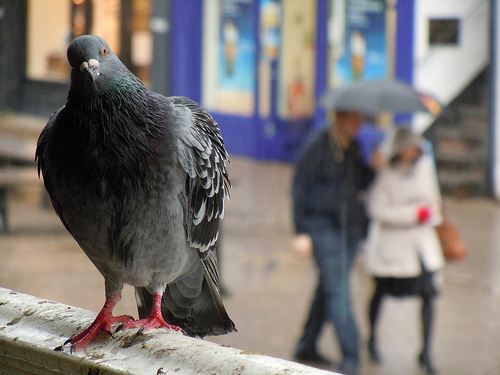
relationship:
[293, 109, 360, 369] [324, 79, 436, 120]
man holds umbrella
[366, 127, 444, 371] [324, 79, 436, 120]
woman holds umbrella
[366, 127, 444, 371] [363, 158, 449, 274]
woman wears coat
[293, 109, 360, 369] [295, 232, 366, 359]
man wears jeans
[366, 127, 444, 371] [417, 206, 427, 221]
woman wears glove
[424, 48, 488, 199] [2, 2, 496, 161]
steps by store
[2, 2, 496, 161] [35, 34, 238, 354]
store behind foreground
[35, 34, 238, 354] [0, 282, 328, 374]
foreground on railing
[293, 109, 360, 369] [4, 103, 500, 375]
man on street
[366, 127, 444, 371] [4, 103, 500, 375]
woman on street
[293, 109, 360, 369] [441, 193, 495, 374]
man walks rightward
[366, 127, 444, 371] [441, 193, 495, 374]
woman walks rightward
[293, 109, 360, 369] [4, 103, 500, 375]
man in street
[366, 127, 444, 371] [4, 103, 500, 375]
woman in street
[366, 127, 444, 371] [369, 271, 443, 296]
woman wears skirt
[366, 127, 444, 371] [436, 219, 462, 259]
woman holds bag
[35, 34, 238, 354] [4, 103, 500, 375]
foreground by street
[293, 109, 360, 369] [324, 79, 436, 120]
man under umbrella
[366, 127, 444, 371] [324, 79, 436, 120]
woman under umbrella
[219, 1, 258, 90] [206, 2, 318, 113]
sign in window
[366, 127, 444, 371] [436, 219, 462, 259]
woman carries bag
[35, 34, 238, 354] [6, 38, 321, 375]
foreground in foreground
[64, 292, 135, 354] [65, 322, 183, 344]
claws have claws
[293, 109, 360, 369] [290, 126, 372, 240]
man wears jacket